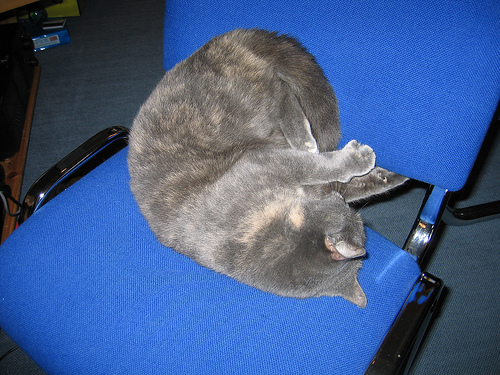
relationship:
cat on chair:
[127, 28, 410, 308] [0, 1, 499, 372]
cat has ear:
[127, 28, 410, 308] [330, 235, 366, 261]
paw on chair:
[335, 138, 375, 184] [0, 1, 499, 372]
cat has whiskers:
[127, 28, 410, 308] [323, 167, 352, 201]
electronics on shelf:
[1, 23, 37, 159] [2, 62, 40, 242]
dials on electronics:
[22, 37, 40, 68] [1, 23, 37, 159]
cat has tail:
[127, 28, 410, 308] [246, 29, 340, 150]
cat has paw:
[127, 28, 410, 308] [335, 138, 375, 184]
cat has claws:
[127, 28, 410, 308] [382, 176, 389, 183]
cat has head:
[127, 28, 410, 308] [295, 190, 370, 308]